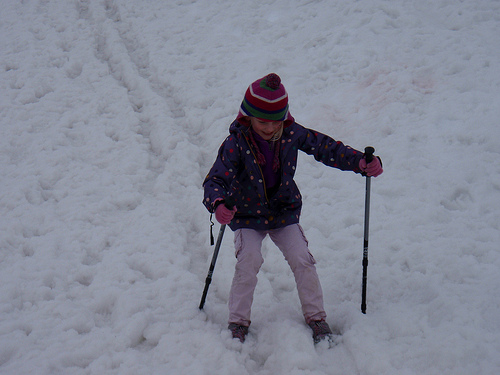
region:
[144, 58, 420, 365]
the kid is skiing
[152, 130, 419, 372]
the kid is holding skipoles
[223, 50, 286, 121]
girl has red hat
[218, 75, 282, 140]
white stripe on hat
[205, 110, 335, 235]
girl has purple coat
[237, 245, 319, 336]
girl has pink pants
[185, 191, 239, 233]
girl has pink gloves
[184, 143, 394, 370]
girl holds black ski poles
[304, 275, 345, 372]
girl has black shoes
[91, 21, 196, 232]
two tracks in snow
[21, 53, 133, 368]
snow is heavy and white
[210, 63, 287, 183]
girl looks at snow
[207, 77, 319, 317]
this is a child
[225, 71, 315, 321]
the child is snow skating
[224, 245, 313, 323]
these are the legs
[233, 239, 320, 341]
the legs are apart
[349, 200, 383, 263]
this is a pole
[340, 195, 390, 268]
the pole is thin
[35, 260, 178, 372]
the place is full of snow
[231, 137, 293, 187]
this is the jacket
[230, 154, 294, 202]
the jacket is warm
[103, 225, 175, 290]
the snow is white in color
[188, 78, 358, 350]
the child is skating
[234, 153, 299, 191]
this is a jacket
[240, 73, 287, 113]
this is a marvin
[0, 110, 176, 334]
the snow is all over the place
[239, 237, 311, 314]
these are the legs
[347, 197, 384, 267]
this is a stick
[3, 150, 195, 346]
the place is full of snow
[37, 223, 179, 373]
the snow is white in color